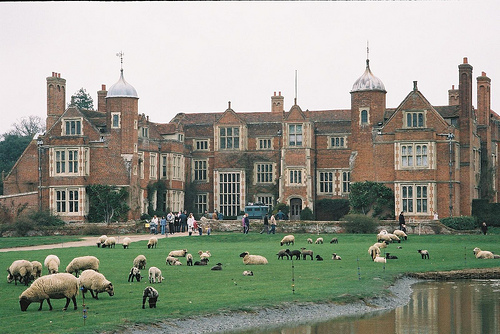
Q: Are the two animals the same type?
A: Yes, all the animals are sheep.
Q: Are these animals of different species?
A: No, all the animals are sheep.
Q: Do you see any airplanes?
A: No, there are no airplanes.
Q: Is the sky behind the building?
A: Yes, the sky is behind the building.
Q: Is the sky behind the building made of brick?
A: Yes, the sky is behind the building.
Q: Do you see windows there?
A: Yes, there is a window.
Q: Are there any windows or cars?
A: Yes, there is a window.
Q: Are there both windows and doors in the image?
A: Yes, there are both a window and a door.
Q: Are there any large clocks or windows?
A: Yes, there is a large window.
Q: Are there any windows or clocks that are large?
A: Yes, the window is large.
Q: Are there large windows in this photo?
A: Yes, there is a large window.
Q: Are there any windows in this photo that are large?
A: Yes, there is a window that is large.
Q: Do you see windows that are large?
A: Yes, there is a window that is large.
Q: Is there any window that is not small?
A: Yes, there is a large window.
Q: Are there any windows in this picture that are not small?
A: Yes, there is a large window.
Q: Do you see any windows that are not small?
A: Yes, there is a large window.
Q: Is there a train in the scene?
A: No, there are no trains.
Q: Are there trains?
A: No, there are no trains.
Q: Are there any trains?
A: No, there are no trains.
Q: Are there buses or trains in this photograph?
A: No, there are no trains or buses.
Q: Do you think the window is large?
A: Yes, the window is large.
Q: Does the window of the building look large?
A: Yes, the window is large.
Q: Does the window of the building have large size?
A: Yes, the window is large.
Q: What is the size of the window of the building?
A: The window is large.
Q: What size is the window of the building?
A: The window is large.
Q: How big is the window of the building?
A: The window is large.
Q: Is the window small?
A: No, the window is large.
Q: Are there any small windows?
A: No, there is a window but it is large.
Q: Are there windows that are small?
A: No, there is a window but it is large.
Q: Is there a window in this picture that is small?
A: No, there is a window but it is large.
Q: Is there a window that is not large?
A: No, there is a window but it is large.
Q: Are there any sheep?
A: Yes, there is a sheep.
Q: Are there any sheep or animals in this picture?
A: Yes, there is a sheep.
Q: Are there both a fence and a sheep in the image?
A: Yes, there are both a sheep and a fence.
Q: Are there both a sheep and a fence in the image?
A: Yes, there are both a sheep and a fence.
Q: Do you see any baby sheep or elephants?
A: Yes, there is a baby sheep.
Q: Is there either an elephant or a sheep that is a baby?
A: Yes, the sheep is a baby.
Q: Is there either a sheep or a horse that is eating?
A: Yes, the sheep is eating.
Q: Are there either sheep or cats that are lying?
A: Yes, the sheep is lying.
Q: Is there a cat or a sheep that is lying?
A: Yes, the sheep is lying.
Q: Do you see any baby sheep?
A: Yes, there is a baby sheep.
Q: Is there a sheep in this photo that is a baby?
A: Yes, there is a sheep that is a baby.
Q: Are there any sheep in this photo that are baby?
A: Yes, there is a sheep that is a baby.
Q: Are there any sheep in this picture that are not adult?
A: Yes, there is an baby sheep.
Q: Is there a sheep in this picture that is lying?
A: Yes, there is a sheep that is lying.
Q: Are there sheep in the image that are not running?
A: Yes, there is a sheep that is lying.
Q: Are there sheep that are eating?
A: Yes, there is a sheep that is eating.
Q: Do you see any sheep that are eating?
A: Yes, there is a sheep that is eating.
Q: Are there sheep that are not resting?
A: Yes, there is a sheep that is eating.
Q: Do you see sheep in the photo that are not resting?
A: Yes, there is a sheep that is eating .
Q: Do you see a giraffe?
A: No, there are no giraffes.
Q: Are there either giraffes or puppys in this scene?
A: No, there are no giraffes or puppys.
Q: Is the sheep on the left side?
A: Yes, the sheep is on the left of the image.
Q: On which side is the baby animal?
A: The sheep is on the left of the image.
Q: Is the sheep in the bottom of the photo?
A: Yes, the sheep is in the bottom of the image.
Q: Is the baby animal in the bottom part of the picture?
A: Yes, the sheep is in the bottom of the image.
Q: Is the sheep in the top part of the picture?
A: No, the sheep is in the bottom of the image.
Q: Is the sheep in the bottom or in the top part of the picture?
A: The sheep is in the bottom of the image.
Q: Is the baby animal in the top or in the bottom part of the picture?
A: The sheep is in the bottom of the image.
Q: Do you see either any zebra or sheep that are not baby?
A: No, there is a sheep but it is a baby.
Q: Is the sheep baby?
A: Yes, the sheep is a baby.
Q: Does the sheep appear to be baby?
A: Yes, the sheep is a baby.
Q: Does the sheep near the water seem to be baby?
A: Yes, the sheep is a baby.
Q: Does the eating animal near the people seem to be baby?
A: Yes, the sheep is a baby.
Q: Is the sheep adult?
A: No, the sheep is a baby.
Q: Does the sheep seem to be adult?
A: No, the sheep is a baby.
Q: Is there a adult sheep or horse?
A: No, there is a sheep but it is a baby.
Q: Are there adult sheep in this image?
A: No, there is a sheep but it is a baby.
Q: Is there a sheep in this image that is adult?
A: No, there is a sheep but it is a baby.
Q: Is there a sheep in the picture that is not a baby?
A: No, there is a sheep but it is a baby.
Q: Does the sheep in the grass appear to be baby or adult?
A: The sheep is a baby.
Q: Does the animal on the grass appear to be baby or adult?
A: The sheep is a baby.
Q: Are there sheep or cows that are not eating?
A: No, there is a sheep but it is eating.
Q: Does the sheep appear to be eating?
A: Yes, the sheep is eating.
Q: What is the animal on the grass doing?
A: The sheep is eating.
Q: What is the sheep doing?
A: The sheep is eating.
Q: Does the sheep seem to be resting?
A: No, the sheep is eating.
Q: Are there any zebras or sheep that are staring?
A: No, there is a sheep but it is eating.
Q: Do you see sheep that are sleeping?
A: No, there is a sheep but it is eating.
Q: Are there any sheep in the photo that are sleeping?
A: No, there is a sheep but it is eating.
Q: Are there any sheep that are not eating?
A: No, there is a sheep but it is eating.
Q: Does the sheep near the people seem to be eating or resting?
A: The sheep is eating.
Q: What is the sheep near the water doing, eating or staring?
A: The sheep is eating.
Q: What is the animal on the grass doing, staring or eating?
A: The sheep is eating.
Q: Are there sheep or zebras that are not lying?
A: No, there is a sheep but it is lying.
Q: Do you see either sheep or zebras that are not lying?
A: No, there is a sheep but it is lying.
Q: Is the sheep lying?
A: Yes, the sheep is lying.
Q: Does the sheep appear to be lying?
A: Yes, the sheep is lying.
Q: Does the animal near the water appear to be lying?
A: Yes, the sheep is lying.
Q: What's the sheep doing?
A: The sheep is lying.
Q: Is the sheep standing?
A: No, the sheep is lying.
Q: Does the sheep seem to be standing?
A: No, the sheep is lying.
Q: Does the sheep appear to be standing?
A: No, the sheep is lying.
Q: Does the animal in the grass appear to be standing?
A: No, the sheep is lying.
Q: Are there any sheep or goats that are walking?
A: No, there is a sheep but it is lying.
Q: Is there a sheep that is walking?
A: No, there is a sheep but it is lying.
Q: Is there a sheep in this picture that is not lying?
A: No, there is a sheep but it is lying.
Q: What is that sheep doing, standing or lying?
A: The sheep is lying.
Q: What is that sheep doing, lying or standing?
A: The sheep is lying.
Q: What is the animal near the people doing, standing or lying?
A: The sheep is lying.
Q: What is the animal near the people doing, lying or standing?
A: The sheep is lying.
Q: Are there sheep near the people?
A: Yes, there is a sheep near the people.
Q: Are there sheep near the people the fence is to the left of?
A: Yes, there is a sheep near the people.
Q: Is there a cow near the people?
A: No, there is a sheep near the people.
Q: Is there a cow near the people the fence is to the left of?
A: No, there is a sheep near the people.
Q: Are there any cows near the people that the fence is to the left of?
A: No, there is a sheep near the people.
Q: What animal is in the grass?
A: The animal is a sheep.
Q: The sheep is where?
A: The sheep is in the grass.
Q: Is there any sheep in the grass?
A: Yes, there is a sheep in the grass.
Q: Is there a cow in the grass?
A: No, there is a sheep in the grass.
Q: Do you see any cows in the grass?
A: No, there is a sheep in the grass.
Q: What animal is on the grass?
A: The animal is a sheep.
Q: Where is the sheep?
A: The sheep is on the grass.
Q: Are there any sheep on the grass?
A: Yes, there is a sheep on the grass.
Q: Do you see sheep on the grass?
A: Yes, there is a sheep on the grass.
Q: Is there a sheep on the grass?
A: Yes, there is a sheep on the grass.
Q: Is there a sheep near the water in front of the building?
A: Yes, there is a sheep near the water.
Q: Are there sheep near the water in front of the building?
A: Yes, there is a sheep near the water.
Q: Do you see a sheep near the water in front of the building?
A: Yes, there is a sheep near the water.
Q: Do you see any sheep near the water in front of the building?
A: Yes, there is a sheep near the water.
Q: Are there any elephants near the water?
A: No, there is a sheep near the water.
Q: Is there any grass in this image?
A: Yes, there is grass.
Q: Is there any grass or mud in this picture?
A: Yes, there is grass.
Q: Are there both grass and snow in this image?
A: No, there is grass but no snow.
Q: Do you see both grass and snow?
A: No, there is grass but no snow.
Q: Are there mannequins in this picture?
A: No, there are no mannequins.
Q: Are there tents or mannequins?
A: No, there are no mannequins or tents.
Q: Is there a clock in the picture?
A: No, there are no clocks.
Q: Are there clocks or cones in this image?
A: No, there are no clocks or cones.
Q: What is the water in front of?
A: The water is in front of the building.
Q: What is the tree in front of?
A: The tree is in front of the building.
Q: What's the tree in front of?
A: The tree is in front of the building.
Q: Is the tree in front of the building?
A: Yes, the tree is in front of the building.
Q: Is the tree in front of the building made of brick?
A: Yes, the tree is in front of the building.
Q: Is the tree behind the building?
A: No, the tree is in front of the building.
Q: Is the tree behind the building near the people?
A: No, the tree is in front of the building.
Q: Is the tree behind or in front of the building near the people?
A: The tree is in front of the building.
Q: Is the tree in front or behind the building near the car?
A: The tree is in front of the building.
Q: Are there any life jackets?
A: No, there are no life jackets.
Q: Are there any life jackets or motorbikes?
A: No, there are no life jackets or motorbikes.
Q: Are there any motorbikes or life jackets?
A: No, there are no life jackets or motorbikes.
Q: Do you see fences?
A: Yes, there is a fence.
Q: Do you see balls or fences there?
A: Yes, there is a fence.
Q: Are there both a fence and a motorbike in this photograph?
A: No, there is a fence but no motorcycles.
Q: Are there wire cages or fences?
A: Yes, there is a wire fence.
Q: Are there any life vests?
A: No, there are no life vests.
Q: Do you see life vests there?
A: No, there are no life vests.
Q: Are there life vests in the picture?
A: No, there are no life vests.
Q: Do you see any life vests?
A: No, there are no life vests.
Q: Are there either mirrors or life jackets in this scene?
A: No, there are no life jackets or mirrors.